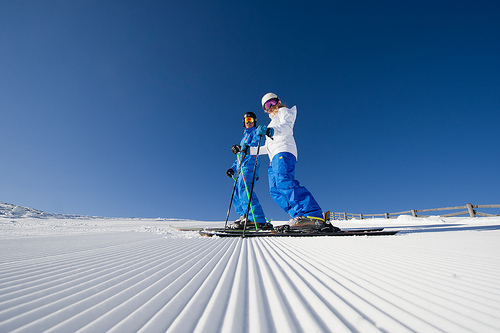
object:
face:
[243, 117, 255, 130]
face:
[261, 98, 278, 117]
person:
[229, 91, 329, 227]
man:
[225, 110, 263, 225]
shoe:
[285, 214, 327, 229]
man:
[226, 89, 336, 233]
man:
[230, 90, 329, 229]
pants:
[268, 151, 321, 218]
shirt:
[250, 103, 299, 157]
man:
[240, 93, 328, 231]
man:
[246, 92, 326, 223]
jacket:
[248, 105, 299, 164]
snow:
[170, 241, 294, 316]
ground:
[16, 248, 481, 329]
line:
[261, 265, 287, 330]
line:
[200, 271, 226, 330]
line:
[168, 286, 199, 331]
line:
[309, 301, 341, 331]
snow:
[20, 241, 480, 329]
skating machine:
[198, 222, 385, 235]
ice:
[198, 237, 398, 263]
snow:
[120, 268, 207, 321]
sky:
[350, 24, 447, 98]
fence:
[397, 205, 481, 226]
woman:
[243, 92, 335, 226]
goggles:
[264, 99, 279, 113]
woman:
[240, 93, 326, 232]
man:
[222, 110, 267, 228]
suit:
[229, 123, 269, 224]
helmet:
[240, 111, 256, 129]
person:
[240, 92, 326, 232]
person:
[225, 110, 265, 231]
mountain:
[0, 202, 172, 331]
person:
[243, 88, 330, 227]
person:
[227, 112, 270, 227]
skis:
[198, 229, 396, 238]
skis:
[177, 224, 381, 234]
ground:
[37, 235, 465, 329]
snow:
[213, 273, 335, 321]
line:
[176, 275, 207, 329]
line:
[193, 276, 222, 330]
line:
[267, 286, 290, 330]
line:
[48, 286, 90, 331]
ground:
[1, 237, 318, 330]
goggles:
[242, 115, 257, 129]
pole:
[245, 139, 265, 231]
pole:
[223, 152, 245, 232]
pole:
[236, 148, 258, 232]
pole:
[231, 169, 235, 187]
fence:
[338, 204, 481, 219]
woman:
[237, 91, 328, 225]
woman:
[226, 113, 267, 228]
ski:
[7, 19, 193, 119]